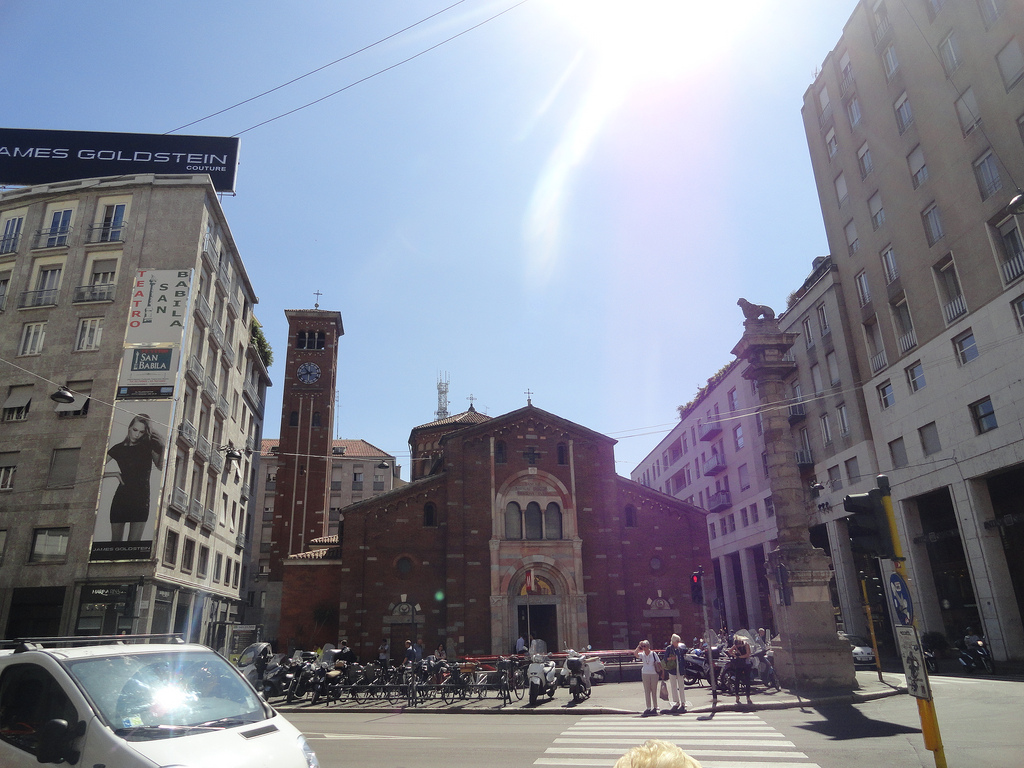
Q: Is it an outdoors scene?
A: Yes, it is outdoors.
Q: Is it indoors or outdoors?
A: It is outdoors.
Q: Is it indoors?
A: No, it is outdoors.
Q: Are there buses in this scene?
A: No, there are no buses.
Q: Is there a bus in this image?
A: No, there are no buses.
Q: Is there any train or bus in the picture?
A: No, there are no buses or trains.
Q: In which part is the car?
A: The car is on the left of the image.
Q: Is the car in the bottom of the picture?
A: Yes, the car is in the bottom of the image.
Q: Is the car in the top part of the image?
A: No, the car is in the bottom of the image.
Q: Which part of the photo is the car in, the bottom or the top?
A: The car is in the bottom of the image.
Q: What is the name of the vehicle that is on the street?
A: The vehicle is a car.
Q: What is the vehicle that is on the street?
A: The vehicle is a car.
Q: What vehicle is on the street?
A: The vehicle is a car.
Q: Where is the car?
A: The car is on the street.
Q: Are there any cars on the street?
A: Yes, there is a car on the street.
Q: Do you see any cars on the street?
A: Yes, there is a car on the street.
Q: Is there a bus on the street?
A: No, there is a car on the street.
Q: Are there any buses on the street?
A: No, there is a car on the street.